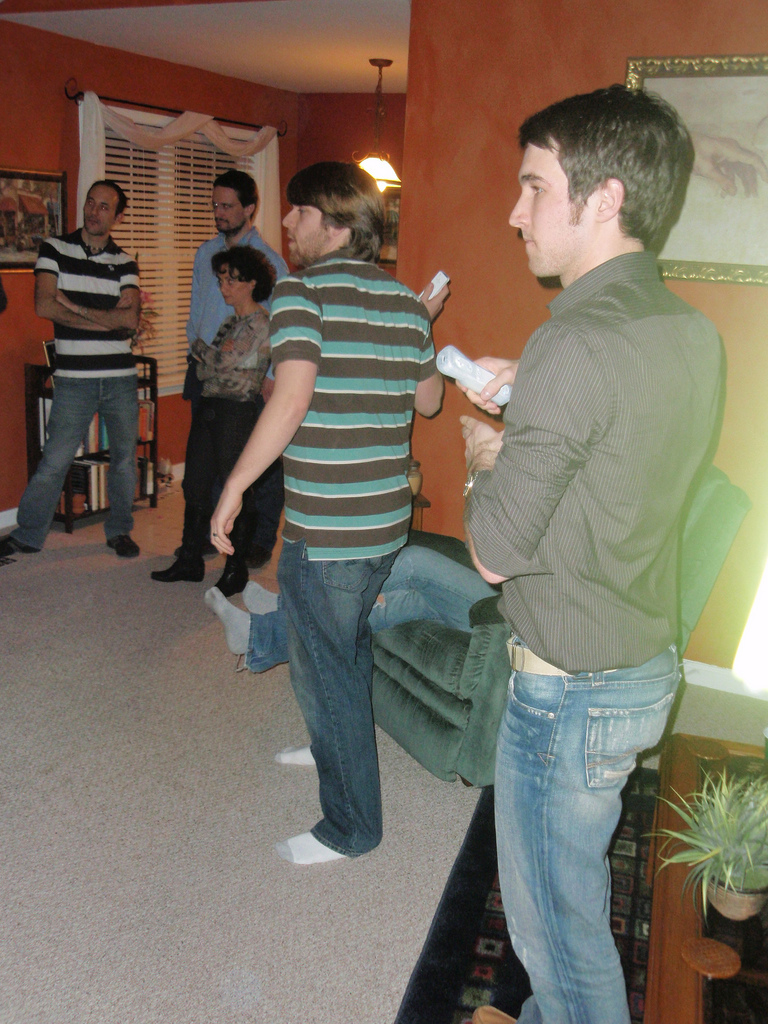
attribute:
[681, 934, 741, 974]
coaster — drink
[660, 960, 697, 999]
table — coffee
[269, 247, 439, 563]
shirt — brown and green striped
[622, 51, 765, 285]
frame — Gold 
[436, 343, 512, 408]
controller — White 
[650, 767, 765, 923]
plant — potted 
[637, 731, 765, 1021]
table — wooden , long 